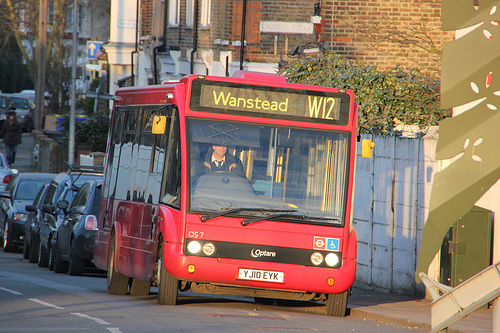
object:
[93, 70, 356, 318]
bus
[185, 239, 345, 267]
light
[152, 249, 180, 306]
tire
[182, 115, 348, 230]
window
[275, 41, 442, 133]
plants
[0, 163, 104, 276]
cars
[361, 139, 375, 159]
mirror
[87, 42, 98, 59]
arrow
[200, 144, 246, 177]
man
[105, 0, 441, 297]
building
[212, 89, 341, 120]
letter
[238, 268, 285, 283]
plate